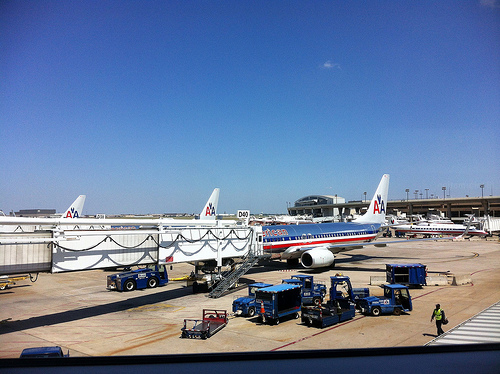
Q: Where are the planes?
A: On a runway.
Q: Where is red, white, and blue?
A: On the plane.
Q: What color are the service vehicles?
A: Blue.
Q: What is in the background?
A: A building.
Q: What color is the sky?
A: Blue.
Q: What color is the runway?
A: Tan.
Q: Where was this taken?
A: Airport.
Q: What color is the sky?
A: Blue.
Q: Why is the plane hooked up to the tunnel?
A: Loading passengers.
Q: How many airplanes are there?
A: 3.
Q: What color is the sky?
A: Blue.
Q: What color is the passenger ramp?
A: White.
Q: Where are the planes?
A: Airport.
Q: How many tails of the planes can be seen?
A: 3.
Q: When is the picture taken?
A: Daytime.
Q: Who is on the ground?
A: A worker.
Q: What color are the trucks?
A: Blue.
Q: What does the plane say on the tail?
A: AA.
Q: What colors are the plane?
A: Red, Blue and White.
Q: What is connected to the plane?
A: Gate.